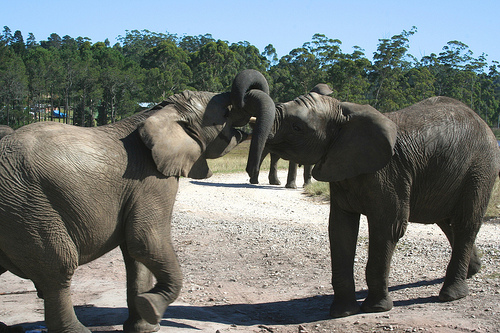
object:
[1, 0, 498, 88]
blue sky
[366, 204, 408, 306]
front leg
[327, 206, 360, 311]
front leg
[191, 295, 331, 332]
elephant shadow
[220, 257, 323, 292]
ground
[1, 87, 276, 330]
elephant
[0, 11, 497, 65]
sky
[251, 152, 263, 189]
leg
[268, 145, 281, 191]
leg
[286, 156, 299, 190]
leg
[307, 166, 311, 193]
leg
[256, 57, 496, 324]
elephant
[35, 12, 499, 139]
trees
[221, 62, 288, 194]
trunks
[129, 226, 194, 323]
leg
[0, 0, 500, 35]
cloud